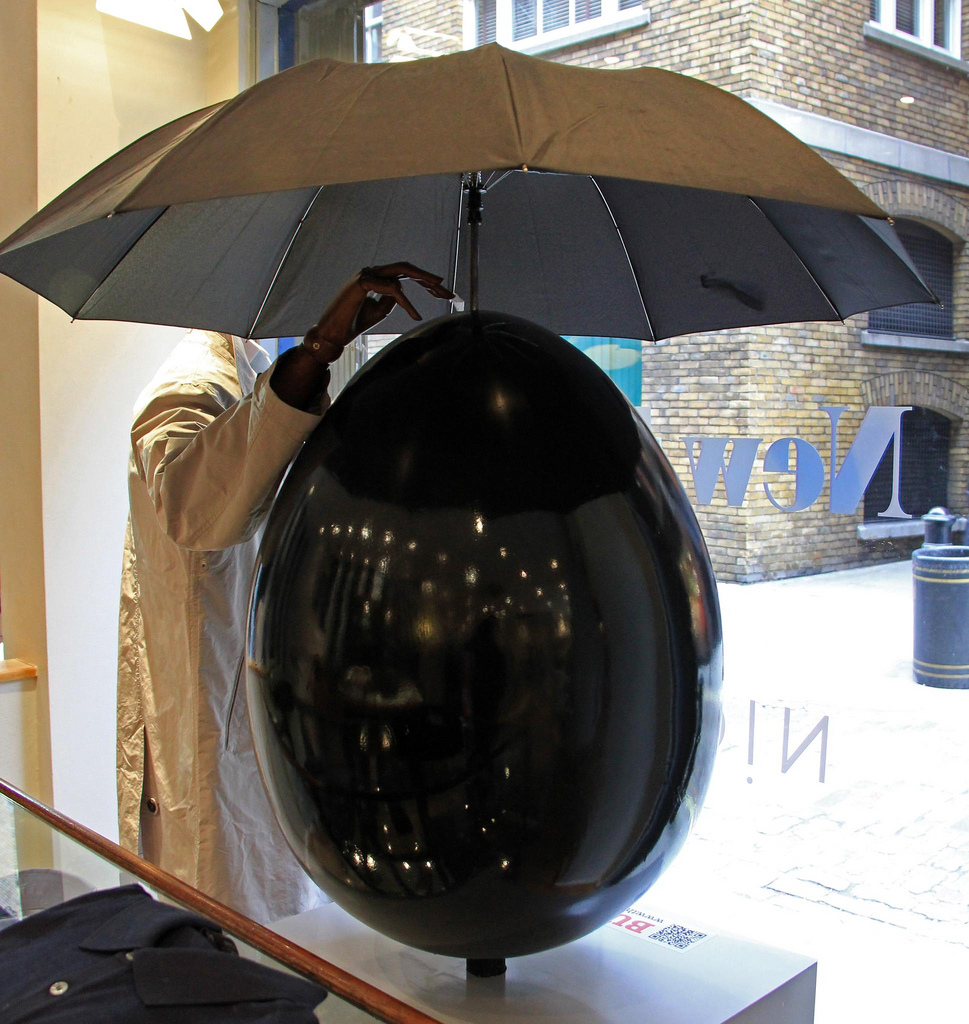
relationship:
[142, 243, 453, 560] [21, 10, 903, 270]
arm raised in air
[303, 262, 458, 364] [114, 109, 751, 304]
hand underneath umbrella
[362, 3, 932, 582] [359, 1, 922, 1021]
building standing outside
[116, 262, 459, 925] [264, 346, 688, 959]
mannequin near egg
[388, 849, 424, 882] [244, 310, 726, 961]
light glare on egg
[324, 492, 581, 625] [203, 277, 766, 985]
lights reflected in egg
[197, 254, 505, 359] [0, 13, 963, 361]
hand under umbrella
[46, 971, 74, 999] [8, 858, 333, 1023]
button on shirt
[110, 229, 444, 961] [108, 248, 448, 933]
mannequin has overcoat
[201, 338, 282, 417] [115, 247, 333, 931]
collar on overcoat